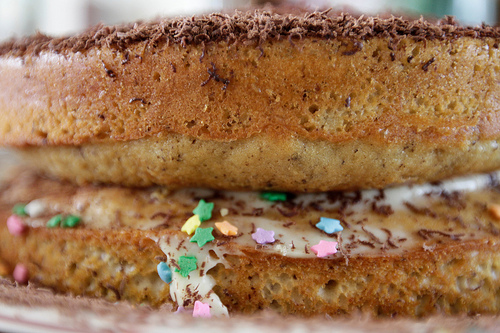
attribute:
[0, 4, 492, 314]
pastry — bread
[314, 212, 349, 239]
star — blue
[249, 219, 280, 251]
sprinkle — pink, star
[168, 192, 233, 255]
sprinkles — star, colorful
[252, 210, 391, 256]
sprinkles — colorful, star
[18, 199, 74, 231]
sprinkles — star, colorful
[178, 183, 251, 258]
sprinkles — colorful, star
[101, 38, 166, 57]
shavings — chocolate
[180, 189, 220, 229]
sprinkle — star, green, small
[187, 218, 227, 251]
sprinkle — green, small, star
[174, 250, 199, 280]
sprinkle — star, small, green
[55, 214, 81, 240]
sprinkle — green, small, star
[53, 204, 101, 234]
sprinkle — star, small, green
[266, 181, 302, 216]
sprinkle — green, small, star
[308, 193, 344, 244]
sprinkle — blue, star, small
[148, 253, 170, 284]
sprinkle — star, small, blue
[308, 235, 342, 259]
sprinkle — pink, small, star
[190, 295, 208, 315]
sprinkle — small, star , pink